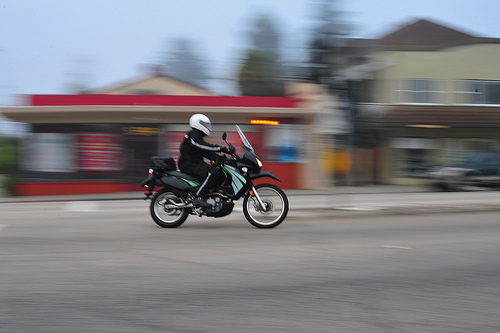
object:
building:
[0, 72, 307, 196]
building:
[320, 12, 497, 188]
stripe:
[190, 137, 222, 152]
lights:
[250, 120, 279, 125]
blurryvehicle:
[429, 157, 499, 192]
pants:
[181, 161, 221, 198]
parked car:
[423, 153, 500, 190]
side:
[0, 182, 499, 212]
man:
[177, 113, 229, 208]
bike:
[139, 125, 289, 229]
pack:
[150, 156, 176, 172]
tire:
[150, 186, 190, 228]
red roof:
[0, 95, 300, 122]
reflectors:
[200, 120, 213, 132]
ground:
[111, 229, 289, 305]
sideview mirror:
[222, 132, 227, 140]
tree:
[235, 9, 292, 101]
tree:
[308, 2, 356, 86]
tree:
[158, 35, 211, 89]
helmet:
[189, 113, 212, 136]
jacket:
[178, 130, 222, 176]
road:
[4, 207, 497, 327]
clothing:
[177, 130, 223, 200]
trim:
[220, 162, 248, 201]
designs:
[221, 164, 246, 197]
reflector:
[195, 172, 214, 196]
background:
[363, 116, 492, 193]